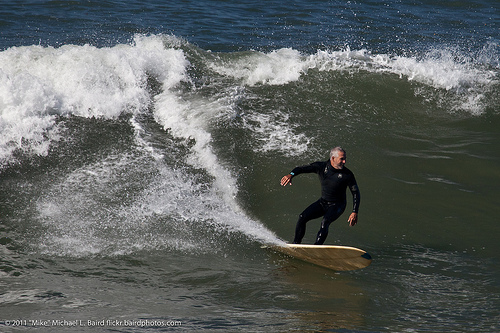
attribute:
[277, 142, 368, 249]
man — looking to left, smiling, turning, surfing, experienced, standing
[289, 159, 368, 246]
wetsuit — black, wet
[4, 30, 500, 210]
waves — splashing, high, white, large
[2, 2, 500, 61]
water — blue, calm, coming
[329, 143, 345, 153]
hair — grey, gray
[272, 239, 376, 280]
surfboard — tan, white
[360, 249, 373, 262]
tip — dark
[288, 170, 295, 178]
bracelet — light blue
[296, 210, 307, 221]
knees — bent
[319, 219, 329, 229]
knees — bent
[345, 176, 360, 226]
arms — outstretched, hanging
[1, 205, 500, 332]
water — muddy, greenish-grey, gray, green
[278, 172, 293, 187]
hand — in air